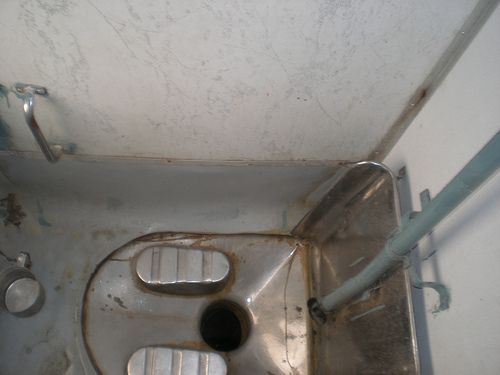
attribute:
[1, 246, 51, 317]
cup — empty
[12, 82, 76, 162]
metal — dirty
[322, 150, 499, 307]
pipe — blue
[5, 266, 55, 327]
cup — silver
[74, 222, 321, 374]
toilet seat — metal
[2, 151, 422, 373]
bathtub — dirty, silver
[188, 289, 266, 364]
holes — ovular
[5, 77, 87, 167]
handle — metal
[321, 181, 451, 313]
pipe — green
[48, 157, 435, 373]
toilet — metal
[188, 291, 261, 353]
hole — very deep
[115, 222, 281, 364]
toilet — squat down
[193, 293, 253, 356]
drain — slanted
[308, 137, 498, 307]
pipe — metal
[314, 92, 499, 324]
pipe — blue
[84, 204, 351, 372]
toilet seat — old, rusty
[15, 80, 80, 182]
handle — chrome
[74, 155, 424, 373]
tub — dirty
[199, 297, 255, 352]
drain — metal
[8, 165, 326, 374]
floor — metal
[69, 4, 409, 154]
wall — white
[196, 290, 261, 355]
hole — dark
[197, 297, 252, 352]
hole — circular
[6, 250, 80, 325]
cup — metal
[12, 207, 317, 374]
floor — metal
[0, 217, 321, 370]
bathtub — dirty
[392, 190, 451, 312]
hinge — blue